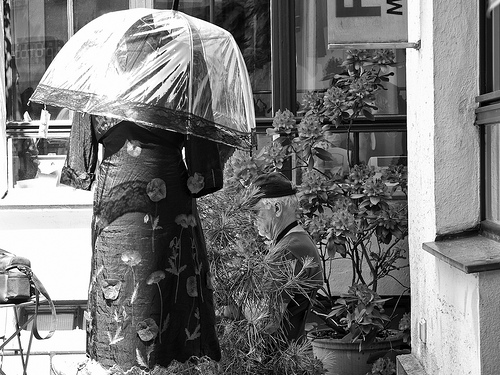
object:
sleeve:
[56, 96, 102, 192]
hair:
[259, 191, 299, 210]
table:
[0, 300, 90, 357]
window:
[430, 1, 500, 265]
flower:
[314, 85, 356, 125]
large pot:
[311, 335, 377, 375]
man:
[229, 173, 320, 368]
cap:
[237, 172, 298, 207]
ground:
[7, 314, 139, 375]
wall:
[390, 0, 500, 375]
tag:
[38, 104, 51, 139]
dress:
[62, 93, 246, 375]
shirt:
[261, 229, 325, 356]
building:
[395, 0, 499, 375]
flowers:
[342, 277, 377, 306]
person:
[64, 17, 238, 370]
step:
[237, 314, 305, 368]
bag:
[0, 255, 59, 343]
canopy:
[24, 7, 264, 154]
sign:
[320, 0, 417, 51]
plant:
[279, 45, 403, 322]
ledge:
[421, 227, 499, 278]